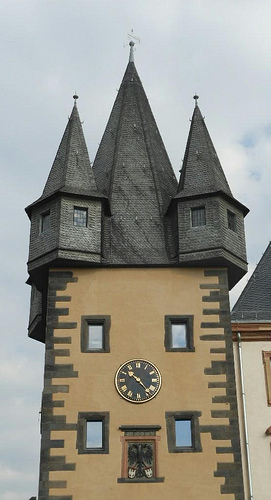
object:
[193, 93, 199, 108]
tip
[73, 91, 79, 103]
tip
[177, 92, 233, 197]
spire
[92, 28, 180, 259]
spire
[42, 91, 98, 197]
spire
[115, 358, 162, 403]
clock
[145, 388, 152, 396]
roman numeral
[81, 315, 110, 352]
window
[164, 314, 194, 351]
window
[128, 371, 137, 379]
hand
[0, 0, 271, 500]
picture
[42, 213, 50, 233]
window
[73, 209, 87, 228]
window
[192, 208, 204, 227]
window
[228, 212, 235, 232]
window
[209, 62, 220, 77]
ground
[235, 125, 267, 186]
clouds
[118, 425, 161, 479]
emblem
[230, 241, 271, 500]
building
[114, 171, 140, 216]
tile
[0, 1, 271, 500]
skys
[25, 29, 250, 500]
tower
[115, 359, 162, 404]
paper holder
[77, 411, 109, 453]
window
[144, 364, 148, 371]
roman numeral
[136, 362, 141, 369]
roman numeral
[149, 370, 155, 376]
roman numeral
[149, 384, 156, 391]
roman numeral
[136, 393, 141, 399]
roman numeral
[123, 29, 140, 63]
tip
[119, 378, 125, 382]
numeral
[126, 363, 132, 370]
numeral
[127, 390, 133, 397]
numeral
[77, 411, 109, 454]
frame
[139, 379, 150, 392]
minute hand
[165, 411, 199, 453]
window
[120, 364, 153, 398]
10:22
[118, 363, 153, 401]
10:23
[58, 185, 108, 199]
roof edge